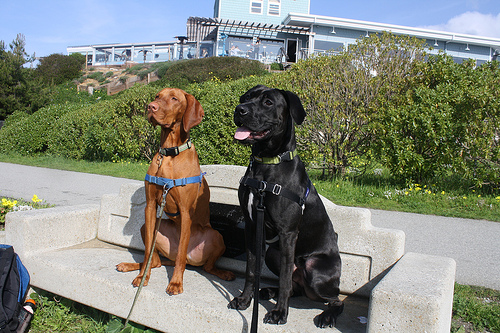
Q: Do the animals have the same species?
A: Yes, all the animals are dogs.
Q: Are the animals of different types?
A: No, all the animals are dogs.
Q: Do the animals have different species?
A: No, all the animals are dogs.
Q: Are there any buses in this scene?
A: No, there are no buses.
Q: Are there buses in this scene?
A: No, there are no buses.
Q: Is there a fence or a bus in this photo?
A: No, there are no buses or fences.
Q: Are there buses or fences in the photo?
A: No, there are no buses or fences.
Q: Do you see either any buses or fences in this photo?
A: No, there are no buses or fences.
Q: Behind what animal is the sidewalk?
A: The sidewalk is behind the dog.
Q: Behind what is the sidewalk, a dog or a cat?
A: The sidewalk is behind a dog.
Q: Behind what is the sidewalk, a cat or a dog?
A: The sidewalk is behind a dog.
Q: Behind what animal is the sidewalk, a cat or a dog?
A: The sidewalk is behind a dog.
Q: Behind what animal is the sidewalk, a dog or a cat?
A: The sidewalk is behind a dog.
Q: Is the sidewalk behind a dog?
A: Yes, the sidewalk is behind a dog.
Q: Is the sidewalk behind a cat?
A: No, the sidewalk is behind a dog.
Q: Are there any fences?
A: No, there are no fences.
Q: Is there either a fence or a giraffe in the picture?
A: No, there are no fences or giraffes.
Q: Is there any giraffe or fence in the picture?
A: No, there are no fences or giraffes.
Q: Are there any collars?
A: Yes, there is a collar.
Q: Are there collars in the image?
A: Yes, there is a collar.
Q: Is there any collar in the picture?
A: Yes, there is a collar.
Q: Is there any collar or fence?
A: Yes, there is a collar.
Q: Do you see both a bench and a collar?
A: Yes, there are both a collar and a bench.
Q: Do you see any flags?
A: No, there are no flags.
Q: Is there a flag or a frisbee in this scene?
A: No, there are no flags or frisbees.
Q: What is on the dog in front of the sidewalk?
A: The collar is on the dog.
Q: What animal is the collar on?
A: The collar is on the dog.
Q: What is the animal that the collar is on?
A: The animal is a dog.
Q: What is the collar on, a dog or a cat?
A: The collar is on a dog.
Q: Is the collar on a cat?
A: No, the collar is on the dog.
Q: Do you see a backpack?
A: Yes, there is a backpack.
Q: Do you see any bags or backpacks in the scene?
A: Yes, there is a backpack.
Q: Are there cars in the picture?
A: No, there are no cars.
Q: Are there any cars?
A: No, there are no cars.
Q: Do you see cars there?
A: No, there are no cars.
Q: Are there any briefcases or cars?
A: No, there are no cars or briefcases.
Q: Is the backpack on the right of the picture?
A: No, the backpack is on the left of the image.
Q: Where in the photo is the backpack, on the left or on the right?
A: The backpack is on the left of the image.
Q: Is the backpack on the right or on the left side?
A: The backpack is on the left of the image.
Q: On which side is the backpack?
A: The backpack is on the left of the image.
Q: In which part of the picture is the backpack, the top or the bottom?
A: The backpack is in the bottom of the image.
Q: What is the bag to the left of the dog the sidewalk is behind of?
A: The bag is a backpack.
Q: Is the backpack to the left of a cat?
A: No, the backpack is to the left of the dog.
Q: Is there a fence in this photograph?
A: No, there are no fences.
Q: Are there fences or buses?
A: No, there are no fences or buses.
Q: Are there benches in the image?
A: Yes, there is a bench.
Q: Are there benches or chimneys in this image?
A: Yes, there is a bench.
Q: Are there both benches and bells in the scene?
A: No, there is a bench but no bells.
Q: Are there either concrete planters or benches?
A: Yes, there is a concrete bench.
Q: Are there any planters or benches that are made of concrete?
A: Yes, the bench is made of concrete.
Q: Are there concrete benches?
A: Yes, there is a bench that is made of concrete.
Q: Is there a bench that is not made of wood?
A: Yes, there is a bench that is made of concrete.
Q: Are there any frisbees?
A: No, there are no frisbees.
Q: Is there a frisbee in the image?
A: No, there are no frisbees.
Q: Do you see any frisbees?
A: No, there are no frisbees.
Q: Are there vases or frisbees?
A: No, there are no frisbees or vases.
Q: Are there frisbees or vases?
A: No, there are no frisbees or vases.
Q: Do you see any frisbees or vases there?
A: No, there are no frisbees or vases.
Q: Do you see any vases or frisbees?
A: No, there are no frisbees or vases.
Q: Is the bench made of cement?
A: Yes, the bench is made of cement.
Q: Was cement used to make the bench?
A: Yes, the bench is made of cement.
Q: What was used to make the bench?
A: The bench is made of cement.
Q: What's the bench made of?
A: The bench is made of concrete.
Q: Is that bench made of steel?
A: No, the bench is made of concrete.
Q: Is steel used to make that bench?
A: No, the bench is made of concrete.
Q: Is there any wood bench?
A: No, there is a bench but it is made of cement.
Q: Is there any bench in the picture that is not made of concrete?
A: No, there is a bench but it is made of concrete.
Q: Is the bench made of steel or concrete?
A: The bench is made of concrete.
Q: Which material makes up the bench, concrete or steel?
A: The bench is made of concrete.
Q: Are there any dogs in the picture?
A: Yes, there is a dog.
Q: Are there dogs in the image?
A: Yes, there is a dog.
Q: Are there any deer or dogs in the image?
A: Yes, there is a dog.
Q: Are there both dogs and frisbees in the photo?
A: No, there is a dog but no frisbees.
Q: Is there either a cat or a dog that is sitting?
A: Yes, the dog is sitting.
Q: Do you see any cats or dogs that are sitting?
A: Yes, the dog is sitting.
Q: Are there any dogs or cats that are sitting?
A: Yes, the dog is sitting.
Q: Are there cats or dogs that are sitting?
A: Yes, the dog is sitting.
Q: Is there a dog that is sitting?
A: Yes, there is a dog that is sitting.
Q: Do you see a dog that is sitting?
A: Yes, there is a dog that is sitting.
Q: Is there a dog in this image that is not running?
A: Yes, there is a dog that is sitting.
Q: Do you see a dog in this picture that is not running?
A: Yes, there is a dog that is sitting .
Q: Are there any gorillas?
A: No, there are no gorillas.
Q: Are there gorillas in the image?
A: No, there are no gorillas.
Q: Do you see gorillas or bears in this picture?
A: No, there are no gorillas or bears.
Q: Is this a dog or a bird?
A: This is a dog.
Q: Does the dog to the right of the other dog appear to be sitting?
A: Yes, the dog is sitting.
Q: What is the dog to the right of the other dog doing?
A: The dog is sitting.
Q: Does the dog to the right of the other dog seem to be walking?
A: No, the dog is sitting.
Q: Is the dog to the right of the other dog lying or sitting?
A: The dog is sitting.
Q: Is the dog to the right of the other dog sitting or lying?
A: The dog is sitting.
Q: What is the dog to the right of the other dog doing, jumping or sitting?
A: The dog is sitting.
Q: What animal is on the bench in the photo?
A: The dog is on the bench.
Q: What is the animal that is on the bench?
A: The animal is a dog.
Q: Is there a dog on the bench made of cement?
A: Yes, there is a dog on the bench.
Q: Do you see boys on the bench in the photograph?
A: No, there is a dog on the bench.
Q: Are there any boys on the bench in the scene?
A: No, there is a dog on the bench.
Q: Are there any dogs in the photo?
A: Yes, there is a dog.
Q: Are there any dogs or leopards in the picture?
A: Yes, there is a dog.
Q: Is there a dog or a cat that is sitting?
A: Yes, the dog is sitting.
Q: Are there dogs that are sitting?
A: Yes, there is a dog that is sitting.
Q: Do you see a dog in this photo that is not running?
A: Yes, there is a dog that is sitting .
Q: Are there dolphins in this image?
A: No, there are no dolphins.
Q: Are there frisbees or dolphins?
A: No, there are no dolphins or frisbees.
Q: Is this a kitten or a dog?
A: This is a dog.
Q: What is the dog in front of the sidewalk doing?
A: The dog is sitting.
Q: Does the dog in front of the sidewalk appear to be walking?
A: No, the dog is sitting.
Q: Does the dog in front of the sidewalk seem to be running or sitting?
A: The dog is sitting.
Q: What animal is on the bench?
A: The dog is on the bench.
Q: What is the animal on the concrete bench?
A: The animal is a dog.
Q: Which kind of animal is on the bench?
A: The animal is a dog.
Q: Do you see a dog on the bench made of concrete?
A: Yes, there is a dog on the bench.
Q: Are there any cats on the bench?
A: No, there is a dog on the bench.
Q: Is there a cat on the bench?
A: No, there is a dog on the bench.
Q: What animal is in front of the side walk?
A: The dog is in front of the side walk.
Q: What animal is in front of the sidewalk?
A: The dog is in front of the side walk.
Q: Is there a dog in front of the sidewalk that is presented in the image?
A: Yes, there is a dog in front of the sidewalk.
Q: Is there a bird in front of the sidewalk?
A: No, there is a dog in front of the sidewalk.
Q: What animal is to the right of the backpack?
A: The animal is a dog.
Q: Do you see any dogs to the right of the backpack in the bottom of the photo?
A: Yes, there is a dog to the right of the backpack.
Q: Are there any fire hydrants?
A: No, there are no fire hydrants.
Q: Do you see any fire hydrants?
A: No, there are no fire hydrants.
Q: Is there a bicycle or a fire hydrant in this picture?
A: No, there are no fire hydrants or bicycles.